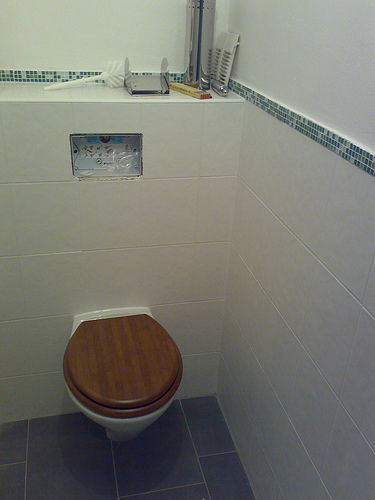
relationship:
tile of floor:
[0, 395, 257, 498] [3, 390, 259, 500]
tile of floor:
[193, 444, 258, 500] [3, 390, 259, 500]